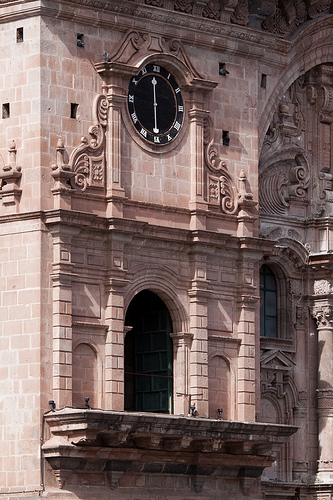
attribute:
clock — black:
[125, 62, 185, 149]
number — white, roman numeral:
[151, 63, 163, 74]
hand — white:
[148, 107, 160, 136]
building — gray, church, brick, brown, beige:
[2, 2, 332, 499]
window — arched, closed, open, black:
[121, 287, 187, 417]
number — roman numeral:
[176, 104, 185, 114]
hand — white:
[148, 76, 159, 107]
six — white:
[151, 135, 162, 148]